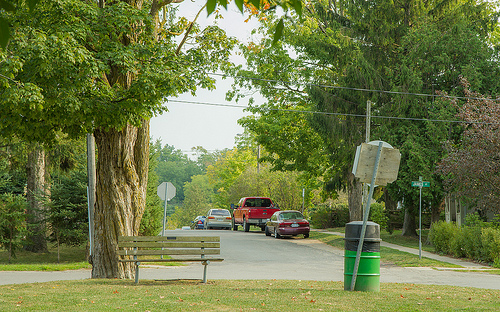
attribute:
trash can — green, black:
[344, 219, 383, 293]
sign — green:
[408, 179, 432, 188]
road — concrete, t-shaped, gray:
[1, 227, 499, 290]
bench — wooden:
[117, 235, 223, 283]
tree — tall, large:
[1, 2, 240, 281]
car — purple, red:
[264, 210, 313, 242]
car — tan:
[206, 208, 234, 230]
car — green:
[191, 213, 207, 230]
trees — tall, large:
[216, 2, 498, 240]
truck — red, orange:
[231, 196, 277, 236]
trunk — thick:
[92, 129, 154, 284]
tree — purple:
[432, 73, 499, 224]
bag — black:
[343, 239, 380, 254]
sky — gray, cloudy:
[144, 3, 321, 165]